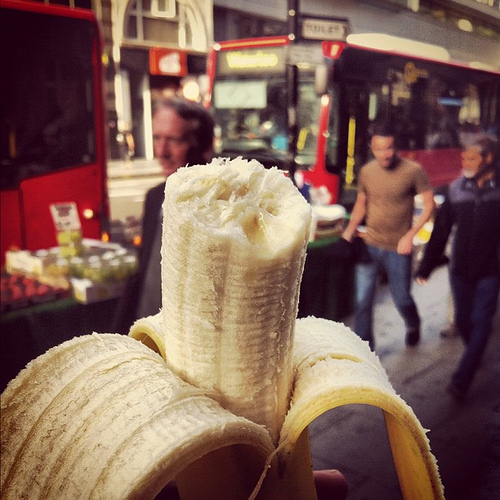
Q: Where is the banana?
A: In a hand.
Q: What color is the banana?
A: Yellow.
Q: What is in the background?
A: Buses.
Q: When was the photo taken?
A: Daytime.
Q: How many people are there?
A: More then two.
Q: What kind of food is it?
A: Banana.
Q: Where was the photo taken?
A: In a metropolitan area.